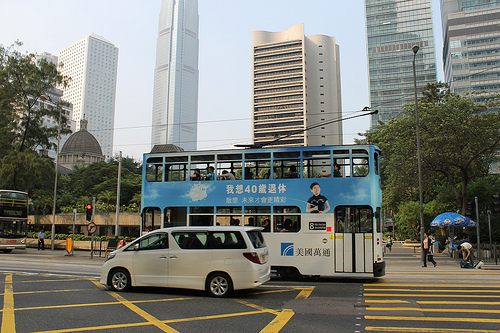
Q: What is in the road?
A: Double decker.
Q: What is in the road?
A: Van.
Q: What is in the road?
A: Cars.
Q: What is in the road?
A: Bus.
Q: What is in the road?
A: Bus.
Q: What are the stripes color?
A: Yellow.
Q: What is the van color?
A: White.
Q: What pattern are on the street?
A: Stripe.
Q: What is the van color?
A: White.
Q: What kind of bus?
A: Double decker.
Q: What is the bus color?
A: Blue.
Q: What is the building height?
A: Tall.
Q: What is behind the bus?
A: A tall building.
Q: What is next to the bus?
A: A white van.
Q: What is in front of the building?
A: A tree.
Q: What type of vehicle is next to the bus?
A: Van.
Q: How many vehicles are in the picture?
A: Three.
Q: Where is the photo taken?
A: Asia.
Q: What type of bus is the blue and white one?
A: Double Decker.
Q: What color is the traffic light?
A: Red.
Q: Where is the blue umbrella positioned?
A: On the sidewalk.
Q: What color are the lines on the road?
A: Yellow.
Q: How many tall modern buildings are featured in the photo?
A: Six.